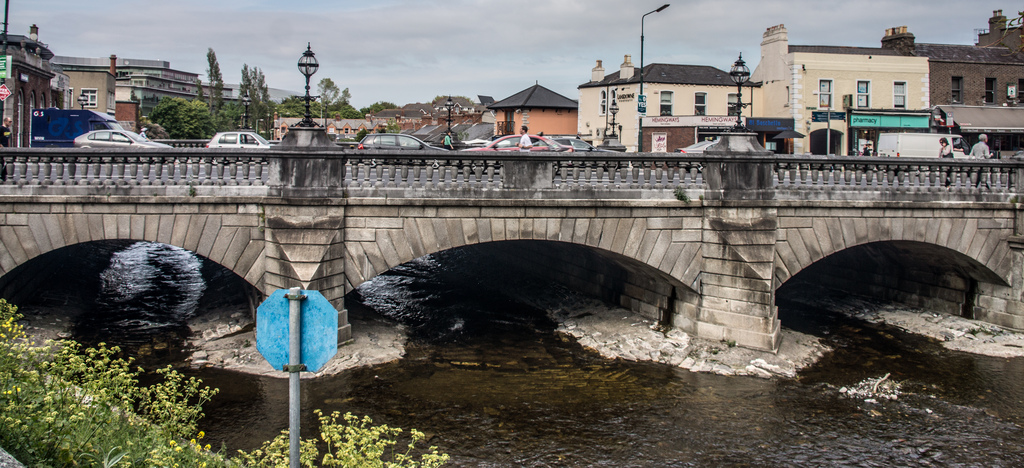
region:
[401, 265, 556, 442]
Water under the overpass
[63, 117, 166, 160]
car on the bridge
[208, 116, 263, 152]
car on the bridge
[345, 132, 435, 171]
car on the bridge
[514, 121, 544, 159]
person walking on the bridge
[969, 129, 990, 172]
person walking on the bridge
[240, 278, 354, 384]
blue sign on the pole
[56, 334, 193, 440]
yellow flowers on the bush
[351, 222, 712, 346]
Scary looking dark alley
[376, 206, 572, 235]
Beautifully arranged stone wall partitions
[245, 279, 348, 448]
Blue colored road sign on post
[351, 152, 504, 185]
Short wooden poles protecting bridge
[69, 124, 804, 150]
Vehicles travelling on top of bridge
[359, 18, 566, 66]
Grey heavy looking clouds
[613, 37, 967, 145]
Buildings beside the bridge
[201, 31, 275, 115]
Long sparse leafed trees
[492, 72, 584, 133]
Maroon colored building with grey roof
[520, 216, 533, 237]
A stone in a wall.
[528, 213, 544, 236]
A stone in a wall.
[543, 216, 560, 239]
A stone in a wall.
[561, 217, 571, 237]
A stone in a wall.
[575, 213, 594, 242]
A stone in a wall.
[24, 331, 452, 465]
an object near the camera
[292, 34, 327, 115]
an object in the distance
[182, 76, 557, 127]
the horizon in the distance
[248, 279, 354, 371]
a blue sign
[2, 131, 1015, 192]
the edge of the bridge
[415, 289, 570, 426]
water under the center part of bridge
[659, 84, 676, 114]
window of building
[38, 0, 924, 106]
sky above the buildings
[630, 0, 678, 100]
the street lamp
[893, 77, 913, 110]
A building in a city.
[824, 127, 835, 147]
A building in a city.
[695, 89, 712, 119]
A building in a city.